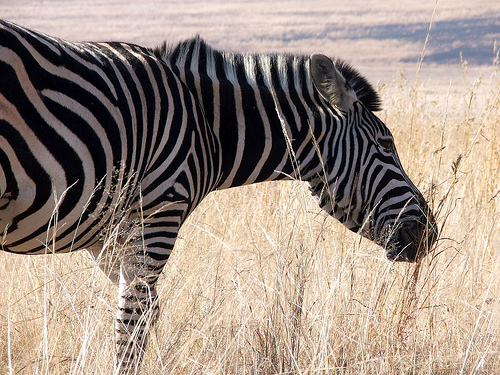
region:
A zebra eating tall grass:
[10, 13, 445, 364]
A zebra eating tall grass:
[7, 7, 442, 362]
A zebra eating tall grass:
[5, 8, 446, 358]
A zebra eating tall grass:
[8, 12, 443, 372]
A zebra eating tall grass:
[2, 8, 442, 363]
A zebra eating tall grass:
[2, 13, 438, 360]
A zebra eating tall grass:
[5, 15, 445, 356]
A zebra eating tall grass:
[12, 12, 444, 353]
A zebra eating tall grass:
[10, 12, 450, 352]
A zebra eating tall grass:
[13, 20, 443, 356]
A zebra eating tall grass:
[13, 12, 448, 343]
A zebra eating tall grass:
[8, 12, 456, 359]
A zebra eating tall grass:
[17, 20, 443, 341]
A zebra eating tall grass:
[8, 23, 455, 353]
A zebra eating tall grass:
[13, 23, 450, 343]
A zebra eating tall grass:
[10, 22, 460, 336]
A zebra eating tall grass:
[15, 25, 456, 345]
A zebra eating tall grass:
[11, 23, 458, 358]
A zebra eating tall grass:
[7, 21, 444, 331]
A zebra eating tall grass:
[6, 21, 446, 346]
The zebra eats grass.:
[4, 11, 444, 369]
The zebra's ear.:
[306, 48, 356, 118]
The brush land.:
[50, 3, 487, 65]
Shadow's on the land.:
[285, 14, 492, 72]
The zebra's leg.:
[117, 234, 157, 368]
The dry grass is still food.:
[216, 225, 431, 352]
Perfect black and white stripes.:
[35, 54, 207, 168]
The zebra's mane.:
[169, 34, 316, 78]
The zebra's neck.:
[218, 122, 315, 194]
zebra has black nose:
[397, 183, 431, 258]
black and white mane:
[111, 44, 366, 106]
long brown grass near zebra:
[212, 235, 424, 362]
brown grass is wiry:
[218, 198, 418, 360]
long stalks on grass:
[395, 85, 492, 299]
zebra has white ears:
[312, 54, 367, 122]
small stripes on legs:
[80, 221, 194, 359]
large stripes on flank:
[5, 78, 140, 193]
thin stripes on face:
[312, 105, 420, 193]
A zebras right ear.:
[306, 52, 357, 111]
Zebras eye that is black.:
[379, 138, 391, 148]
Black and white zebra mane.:
[151, 32, 383, 112]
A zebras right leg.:
[113, 196, 190, 374]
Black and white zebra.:
[0, 16, 437, 373]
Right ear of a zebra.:
[309, 51, 354, 113]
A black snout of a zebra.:
[389, 210, 439, 262]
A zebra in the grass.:
[9, 21, 451, 373]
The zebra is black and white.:
[6, 18, 436, 368]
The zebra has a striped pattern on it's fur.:
[6, 20, 453, 367]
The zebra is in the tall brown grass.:
[4, 19, 451, 369]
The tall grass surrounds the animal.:
[22, 105, 489, 370]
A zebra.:
[1, 18, 430, 360]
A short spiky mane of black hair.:
[326, 53, 390, 113]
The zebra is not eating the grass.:
[3, 21, 443, 369]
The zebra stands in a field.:
[12, 5, 499, 372]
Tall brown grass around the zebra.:
[5, 65, 485, 374]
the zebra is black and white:
[18, 9, 468, 366]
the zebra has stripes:
[3, 3, 460, 355]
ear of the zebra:
[296, 43, 347, 110]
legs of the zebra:
[88, 205, 181, 374]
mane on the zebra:
[103, 30, 378, 122]